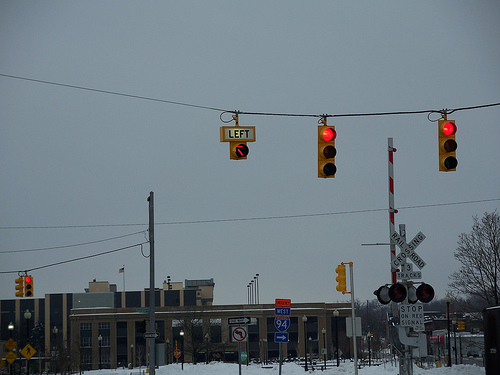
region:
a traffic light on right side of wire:
[418, 99, 470, 182]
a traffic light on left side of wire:
[313, 101, 353, 186]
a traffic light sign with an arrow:
[213, 112, 265, 169]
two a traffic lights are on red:
[294, 99, 466, 198]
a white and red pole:
[365, 131, 441, 370]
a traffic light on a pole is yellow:
[328, 250, 370, 372]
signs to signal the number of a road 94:
[264, 291, 295, 370]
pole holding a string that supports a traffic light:
[130, 180, 177, 370]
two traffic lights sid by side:
[7, 261, 47, 307]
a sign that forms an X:
[383, 224, 434, 275]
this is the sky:
[51, 113, 117, 168]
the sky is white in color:
[38, 115, 136, 181]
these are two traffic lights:
[298, 110, 490, 195]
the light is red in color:
[321, 127, 333, 140]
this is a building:
[20, 281, 361, 363]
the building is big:
[0, 285, 336, 344]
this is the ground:
[208, 365, 236, 373]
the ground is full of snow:
[187, 363, 235, 373]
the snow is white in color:
[191, 362, 226, 374]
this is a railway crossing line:
[378, 226, 433, 276]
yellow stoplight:
[303, 91, 341, 193]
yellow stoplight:
[316, 87, 382, 249]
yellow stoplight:
[313, 104, 362, 202]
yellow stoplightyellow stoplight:
[301, 101, 358, 198]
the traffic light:
[271, 111, 358, 243]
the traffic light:
[309, 111, 431, 198]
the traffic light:
[279, 41, 354, 213]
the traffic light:
[291, 65, 366, 297]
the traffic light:
[311, 75, 377, 237]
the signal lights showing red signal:
[424, 97, 473, 183]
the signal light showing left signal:
[205, 93, 269, 175]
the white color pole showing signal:
[326, 248, 371, 374]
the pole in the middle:
[129, 164, 181, 372]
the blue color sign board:
[270, 277, 306, 371]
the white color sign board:
[367, 199, 448, 367]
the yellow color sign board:
[5, 335, 40, 373]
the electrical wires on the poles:
[56, 219, 136, 271]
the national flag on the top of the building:
[116, 261, 133, 291]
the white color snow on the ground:
[205, 363, 219, 374]